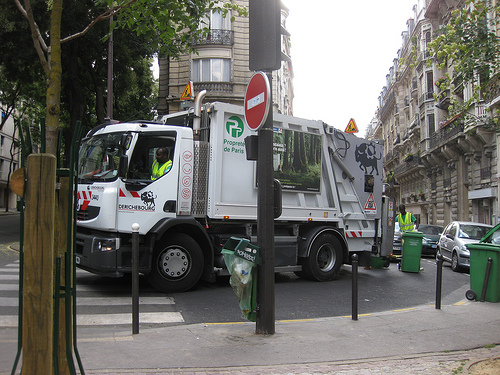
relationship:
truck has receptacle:
[68, 86, 395, 287] [315, 118, 394, 256]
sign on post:
[238, 66, 274, 134] [253, 67, 280, 332]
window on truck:
[78, 134, 127, 173] [68, 86, 395, 287]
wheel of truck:
[147, 221, 208, 290] [68, 86, 395, 287]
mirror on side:
[113, 151, 131, 182] [120, 121, 194, 250]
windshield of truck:
[78, 134, 127, 173] [68, 86, 395, 287]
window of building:
[187, 55, 235, 82] [158, 2, 294, 108]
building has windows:
[158, 2, 294, 108] [187, 55, 235, 82]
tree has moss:
[4, 3, 205, 170] [45, 3, 64, 118]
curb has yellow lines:
[280, 297, 475, 324] [359, 302, 420, 318]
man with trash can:
[393, 201, 418, 233] [396, 229, 424, 275]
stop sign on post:
[238, 66, 274, 134] [253, 67, 274, 336]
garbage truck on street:
[68, 86, 395, 287] [1, 259, 458, 339]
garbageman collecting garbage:
[393, 201, 418, 233] [396, 229, 424, 275]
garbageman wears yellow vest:
[393, 201, 418, 233] [394, 211, 417, 231]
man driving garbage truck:
[150, 145, 174, 180] [68, 86, 395, 287]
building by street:
[391, 10, 499, 215] [1, 259, 458, 339]